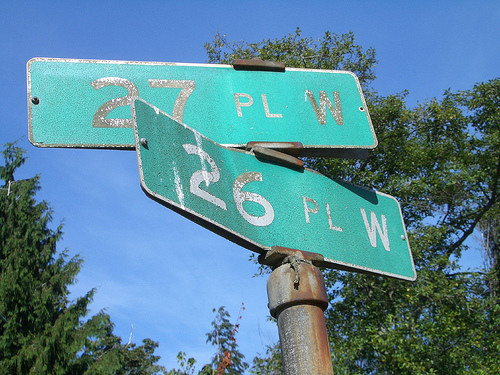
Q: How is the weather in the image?
A: It is clear.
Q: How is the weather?
A: It is clear.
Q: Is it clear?
A: Yes, it is clear.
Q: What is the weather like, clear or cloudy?
A: It is clear.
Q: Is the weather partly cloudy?
A: No, it is clear.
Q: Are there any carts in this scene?
A: No, there are no carts.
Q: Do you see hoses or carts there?
A: No, there are no carts or hoses.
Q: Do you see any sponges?
A: No, there are no sponges.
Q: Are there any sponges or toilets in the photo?
A: No, there are no sponges or toilets.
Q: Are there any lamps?
A: No, there are no lamps.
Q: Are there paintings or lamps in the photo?
A: No, there are no lamps or paintings.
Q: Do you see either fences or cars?
A: No, there are no fences or cars.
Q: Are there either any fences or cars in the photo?
A: No, there are no fences or cars.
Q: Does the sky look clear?
A: Yes, the sky is clear.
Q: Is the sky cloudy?
A: No, the sky is clear.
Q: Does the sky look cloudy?
A: No, the sky is clear.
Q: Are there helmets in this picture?
A: No, there are no helmets.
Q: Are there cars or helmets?
A: No, there are no helmets or cars.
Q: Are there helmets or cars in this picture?
A: No, there are no helmets or cars.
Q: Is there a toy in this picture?
A: No, there are no toys.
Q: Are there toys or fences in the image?
A: No, there are no toys or fences.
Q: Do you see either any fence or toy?
A: No, there are no toys or fences.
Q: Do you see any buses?
A: No, there are no buses.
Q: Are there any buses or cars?
A: No, there are no buses or cars.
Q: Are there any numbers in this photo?
A: Yes, there are numbers.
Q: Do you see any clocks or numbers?
A: Yes, there are numbers.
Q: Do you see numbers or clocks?
A: Yes, there are numbers.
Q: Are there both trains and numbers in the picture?
A: No, there are numbers but no trains.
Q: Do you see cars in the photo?
A: No, there are no cars.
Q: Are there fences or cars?
A: No, there are no cars or fences.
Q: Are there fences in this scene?
A: No, there are no fences.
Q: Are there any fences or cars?
A: No, there are no fences or cars.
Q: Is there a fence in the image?
A: No, there are no fences.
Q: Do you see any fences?
A: No, there are no fences.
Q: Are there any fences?
A: No, there are no fences.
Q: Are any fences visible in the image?
A: No, there are no fences.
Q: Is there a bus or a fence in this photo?
A: No, there are no fences or buses.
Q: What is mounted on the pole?
A: The sign is mounted on the pole.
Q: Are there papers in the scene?
A: No, there are no papers.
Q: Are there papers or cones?
A: No, there are no papers or cones.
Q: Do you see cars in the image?
A: No, there are no cars.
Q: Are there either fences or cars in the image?
A: No, there are no cars or fences.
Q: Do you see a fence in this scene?
A: No, there are no fences.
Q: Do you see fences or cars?
A: No, there are no fences or cars.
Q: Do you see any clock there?
A: No, there are no clocks.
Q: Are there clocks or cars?
A: No, there are no clocks or cars.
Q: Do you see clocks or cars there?
A: No, there are no clocks or cars.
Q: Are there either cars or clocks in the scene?
A: No, there are no clocks or cars.